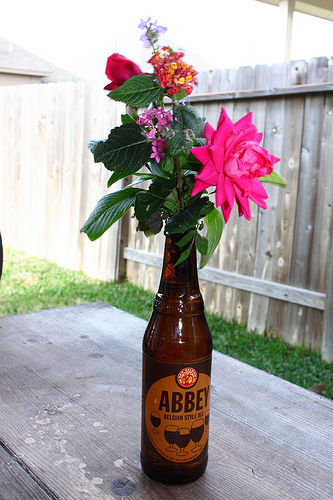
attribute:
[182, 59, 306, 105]
plank — wooden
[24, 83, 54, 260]
plank — wooden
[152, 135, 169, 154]
flower — small, pink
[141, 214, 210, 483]
bottle — glass, brown, beer, orange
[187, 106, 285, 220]
flower — bright pink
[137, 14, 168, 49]
flowers — purple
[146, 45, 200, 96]
flowers — orange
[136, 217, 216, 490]
bottle — brown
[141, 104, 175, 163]
pink flower — small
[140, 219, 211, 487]
beer bottle — reused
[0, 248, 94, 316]
green lawn — in the shade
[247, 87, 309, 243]
plank — wooden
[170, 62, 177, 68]
yellow flower — tiny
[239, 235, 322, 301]
fence — wooden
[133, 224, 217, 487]
beer bottle — brown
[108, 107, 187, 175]
leaf — green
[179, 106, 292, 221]
flower — large , pink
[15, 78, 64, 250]
plank — wooden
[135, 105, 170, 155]
flower — small, pink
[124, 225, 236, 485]
beer bottle — brown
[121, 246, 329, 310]
plank — wooden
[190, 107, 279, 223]
flower — pink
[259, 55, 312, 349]
plank — wooden